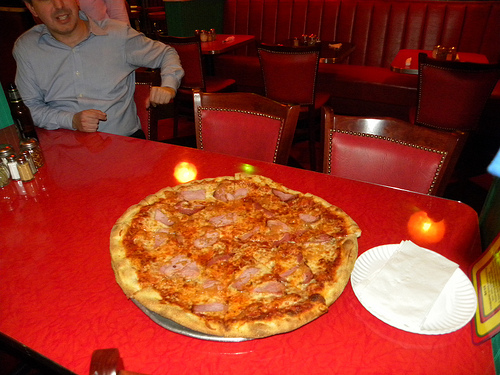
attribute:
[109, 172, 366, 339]
pizza — huge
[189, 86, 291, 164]
chair — red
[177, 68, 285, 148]
chair — red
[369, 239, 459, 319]
napkins — white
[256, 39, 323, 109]
chair — red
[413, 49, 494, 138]
chair — red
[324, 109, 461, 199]
chair — red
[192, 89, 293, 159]
chair — red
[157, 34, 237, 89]
chair — red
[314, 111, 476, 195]
chairs — red, brown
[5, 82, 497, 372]
table — red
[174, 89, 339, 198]
chair — red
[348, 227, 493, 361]
plate — white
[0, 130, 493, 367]
table — red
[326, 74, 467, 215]
chair — wood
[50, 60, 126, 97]
shirt — gray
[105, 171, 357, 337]
crust — golden brown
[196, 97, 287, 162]
chair — red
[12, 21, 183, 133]
shirt — long sleeve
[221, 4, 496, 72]
wall — brown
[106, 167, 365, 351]
pizza — whole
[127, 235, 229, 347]
pizza slice — triangle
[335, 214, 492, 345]
plate — paper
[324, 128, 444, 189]
padding — cloth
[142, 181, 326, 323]
pizza — large